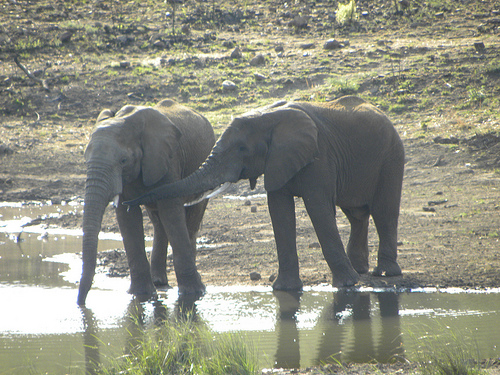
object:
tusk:
[205, 180, 234, 201]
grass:
[81, 300, 265, 374]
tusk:
[181, 190, 212, 207]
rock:
[247, 269, 260, 281]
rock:
[218, 78, 238, 94]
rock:
[321, 36, 340, 52]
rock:
[472, 40, 485, 52]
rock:
[50, 194, 62, 205]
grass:
[0, 0, 500, 286]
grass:
[336, 1, 360, 29]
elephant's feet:
[127, 270, 158, 296]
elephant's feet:
[266, 268, 308, 291]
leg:
[263, 195, 301, 273]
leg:
[339, 200, 372, 256]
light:
[205, 302, 318, 332]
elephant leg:
[370, 167, 403, 259]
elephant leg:
[155, 196, 201, 281]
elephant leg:
[145, 203, 170, 273]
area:
[0, 0, 500, 287]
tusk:
[108, 195, 120, 208]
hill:
[0, 0, 500, 169]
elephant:
[76, 96, 222, 306]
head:
[121, 105, 320, 208]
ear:
[264, 106, 320, 192]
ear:
[125, 106, 182, 190]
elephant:
[119, 97, 404, 292]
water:
[0, 200, 500, 374]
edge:
[306, 277, 500, 294]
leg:
[114, 201, 153, 279]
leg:
[303, 199, 353, 271]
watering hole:
[0, 192, 500, 373]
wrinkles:
[83, 176, 112, 188]